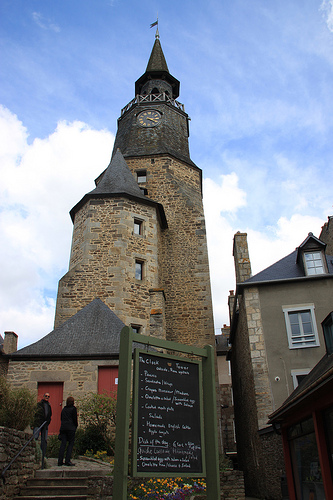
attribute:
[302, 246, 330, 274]
window — white 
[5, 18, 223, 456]
clock tower — old, stone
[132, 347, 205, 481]
frame — green 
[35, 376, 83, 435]
door — red 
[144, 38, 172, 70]
roof — dark 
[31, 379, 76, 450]
door — red 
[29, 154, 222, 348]
buildings — stone 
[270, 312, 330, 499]
building — red 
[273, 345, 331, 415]
roof — dark 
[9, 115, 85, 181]
clouds — faint 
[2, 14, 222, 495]
building — rock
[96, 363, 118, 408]
door — red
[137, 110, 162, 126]
clock — black 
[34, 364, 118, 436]
doors — red 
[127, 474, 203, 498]
flowers — yellow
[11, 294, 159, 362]
roof — pointed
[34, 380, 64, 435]
door — red 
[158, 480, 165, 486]
flower — colored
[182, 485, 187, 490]
flower — colored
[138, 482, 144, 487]
flower — colored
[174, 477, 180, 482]
flower — colored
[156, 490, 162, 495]
flower — colored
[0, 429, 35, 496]
wall — stone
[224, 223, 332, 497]
building — gray , stone 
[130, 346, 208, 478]
sign — wood, chalkboard, black, chalkboard sign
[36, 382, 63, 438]
door — red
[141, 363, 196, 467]
writing — white